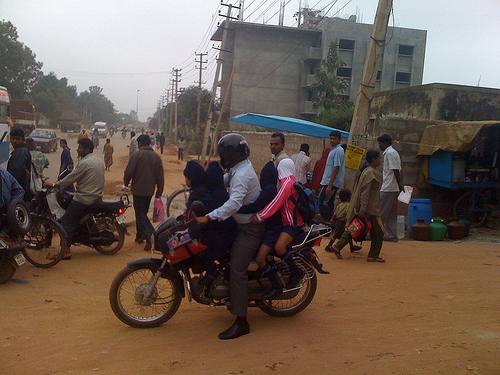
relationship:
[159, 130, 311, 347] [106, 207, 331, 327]
four people ride motorcycle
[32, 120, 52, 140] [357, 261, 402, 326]
cars driving on road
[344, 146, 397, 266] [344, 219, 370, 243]
woman carrying bag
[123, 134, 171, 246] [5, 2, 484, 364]
person in town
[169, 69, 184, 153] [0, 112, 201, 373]
pole along street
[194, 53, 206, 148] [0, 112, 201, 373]
pole along street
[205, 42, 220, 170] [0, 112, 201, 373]
pole along street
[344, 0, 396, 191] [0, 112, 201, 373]
eletrical poles along street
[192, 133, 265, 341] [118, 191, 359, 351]
man on motorcycle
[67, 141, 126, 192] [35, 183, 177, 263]
man on motorcycle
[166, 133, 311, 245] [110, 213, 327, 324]
family on motorcycle